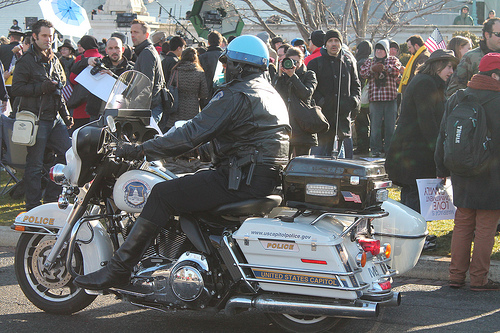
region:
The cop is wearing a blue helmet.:
[212, 30, 274, 74]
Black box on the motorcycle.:
[286, 144, 396, 217]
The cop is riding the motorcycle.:
[132, 39, 334, 229]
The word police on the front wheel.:
[14, 208, 65, 228]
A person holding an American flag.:
[406, 27, 460, 59]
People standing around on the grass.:
[269, 9, 473, 155]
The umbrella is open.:
[21, 2, 98, 35]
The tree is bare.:
[241, 0, 421, 32]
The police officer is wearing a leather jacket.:
[186, 80, 286, 140]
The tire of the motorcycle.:
[9, 223, 89, 328]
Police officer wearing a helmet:
[204, 23, 274, 84]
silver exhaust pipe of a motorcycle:
[244, 281, 395, 328]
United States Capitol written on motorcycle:
[249, 262, 346, 295]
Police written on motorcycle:
[15, 208, 62, 231]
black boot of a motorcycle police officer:
[63, 197, 166, 303]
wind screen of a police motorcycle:
[76, 60, 164, 139]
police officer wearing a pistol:
[217, 144, 261, 198]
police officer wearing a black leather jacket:
[129, 68, 307, 186]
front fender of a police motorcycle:
[10, 205, 126, 318]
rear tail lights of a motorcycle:
[356, 231, 400, 273]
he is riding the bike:
[214, 169, 266, 209]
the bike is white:
[249, 246, 284, 276]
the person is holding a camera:
[280, 54, 298, 76]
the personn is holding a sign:
[428, 171, 450, 194]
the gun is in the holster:
[223, 148, 258, 180]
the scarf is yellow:
[402, 56, 417, 70]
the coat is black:
[241, 96, 259, 126]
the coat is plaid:
[372, 84, 389, 96]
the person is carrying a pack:
[453, 86, 497, 153]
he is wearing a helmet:
[229, 45, 251, 73]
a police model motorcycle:
[8, 66, 430, 331]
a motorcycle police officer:
[68, 32, 299, 295]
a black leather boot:
[66, 209, 169, 292]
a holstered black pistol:
[223, 145, 258, 194]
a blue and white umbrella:
[39, 1, 90, 43]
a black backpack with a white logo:
[437, 81, 496, 183]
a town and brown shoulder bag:
[11, 72, 48, 150]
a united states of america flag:
[338, 187, 365, 207]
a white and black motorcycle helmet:
[220, 27, 281, 86]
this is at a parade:
[8, 3, 459, 280]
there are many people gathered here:
[25, 37, 346, 319]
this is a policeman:
[74, 39, 425, 301]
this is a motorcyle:
[94, 143, 402, 329]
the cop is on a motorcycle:
[31, 86, 384, 297]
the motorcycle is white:
[45, 171, 354, 301]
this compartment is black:
[277, 144, 374, 198]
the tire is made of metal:
[5, 240, 92, 315]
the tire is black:
[0, 274, 83, 304]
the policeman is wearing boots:
[68, 206, 200, 287]